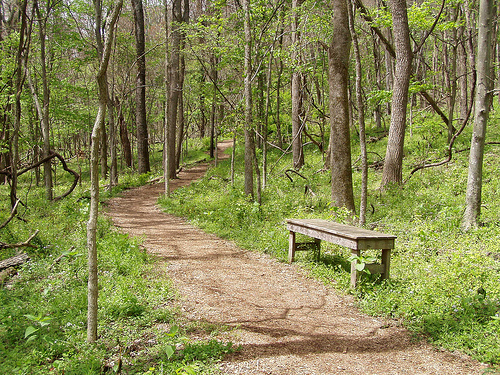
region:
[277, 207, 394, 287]
Light brown bench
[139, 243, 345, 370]
Brown dirth walkway path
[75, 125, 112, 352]
Skinny brown tree bark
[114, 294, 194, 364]
Patch of bright green grass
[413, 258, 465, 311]
Patch of bright green grass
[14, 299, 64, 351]
Patch of bright green grass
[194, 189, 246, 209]
Patch of bright green grass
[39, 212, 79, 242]
Patch of bright green grass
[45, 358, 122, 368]
Patch of bright green grass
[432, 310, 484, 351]
Patch of bright green grass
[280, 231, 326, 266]
Right legs of wooden bench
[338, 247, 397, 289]
Left legs of wooden bench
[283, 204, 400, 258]
Seat of wooden bench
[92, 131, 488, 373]
Dirt path in forest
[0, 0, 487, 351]
Brown trunks of trees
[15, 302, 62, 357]
Green leafy plant on ground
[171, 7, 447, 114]
Green leaves on trees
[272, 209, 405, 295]
Bench sitting next to path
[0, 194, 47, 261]
Brown branches of tree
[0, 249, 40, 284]
Brown log on ground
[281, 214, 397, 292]
a bench on the side of a path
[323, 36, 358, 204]
a trunk of a tree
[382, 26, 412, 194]
a trunk of a tree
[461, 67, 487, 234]
a trunk of a tree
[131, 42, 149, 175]
a trunk of a tree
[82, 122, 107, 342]
a trunk of a tree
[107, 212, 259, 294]
a dirt walking trail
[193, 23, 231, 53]
the leaves of a tree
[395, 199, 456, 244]
weeds in the woods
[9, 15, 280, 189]
a dirt trail through the woods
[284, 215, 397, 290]
wooden bench along wooded path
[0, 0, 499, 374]
woods filled with many thin trees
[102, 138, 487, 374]
path is wide and made of dirt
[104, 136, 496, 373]
dirt path winds through trees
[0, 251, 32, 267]
dead log laying in grass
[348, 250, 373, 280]
wild green plant by bench leg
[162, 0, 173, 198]
tall thin tree growing almost in path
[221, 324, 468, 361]
wide dark shadow on path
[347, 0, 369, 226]
tall thin tree behind wooden bench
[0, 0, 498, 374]
wooded path and grassy areas are secluded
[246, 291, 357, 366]
shadow is on the ground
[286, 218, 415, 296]
the bench is woden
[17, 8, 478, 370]
the scene is outdoors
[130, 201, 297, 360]
a path is between the forest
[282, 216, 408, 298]
no one is on the bench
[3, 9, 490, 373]
the sun is shining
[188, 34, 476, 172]
the tree bark is grey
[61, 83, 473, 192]
the trees are few meters apart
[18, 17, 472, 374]
the scene was taken during the day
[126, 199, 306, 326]
the path is unpaved